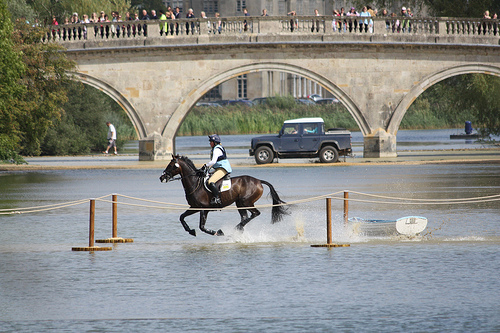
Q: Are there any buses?
A: No, there are no buses.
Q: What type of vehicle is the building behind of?
A: The building is behind the cars.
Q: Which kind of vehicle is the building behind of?
A: The building is behind the cars.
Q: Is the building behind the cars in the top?
A: Yes, the building is behind the cars.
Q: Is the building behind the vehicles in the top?
A: Yes, the building is behind the cars.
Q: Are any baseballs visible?
A: No, there are no baseballs.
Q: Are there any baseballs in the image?
A: No, there are no baseballs.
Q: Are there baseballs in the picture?
A: No, there are no baseballs.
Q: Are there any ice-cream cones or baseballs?
A: No, there are no baseballs or ice-cream cones.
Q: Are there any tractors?
A: No, there are no tractors.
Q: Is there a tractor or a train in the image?
A: No, there are no tractors or trains.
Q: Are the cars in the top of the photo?
A: Yes, the cars are in the top of the image.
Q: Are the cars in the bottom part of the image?
A: No, the cars are in the top of the image.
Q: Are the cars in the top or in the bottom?
A: The cars are in the top of the image.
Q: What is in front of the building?
A: The cars are in front of the building.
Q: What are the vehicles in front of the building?
A: The vehicles are cars.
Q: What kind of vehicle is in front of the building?
A: The vehicles are cars.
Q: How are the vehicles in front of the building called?
A: The vehicles are cars.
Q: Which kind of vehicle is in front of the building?
A: The vehicles are cars.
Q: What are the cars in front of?
A: The cars are in front of the building.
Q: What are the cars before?
A: The cars are in front of the building.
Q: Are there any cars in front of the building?
A: Yes, there are cars in front of the building.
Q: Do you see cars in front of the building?
A: Yes, there are cars in front of the building.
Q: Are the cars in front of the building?
A: Yes, the cars are in front of the building.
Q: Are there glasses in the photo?
A: No, there are no glasses.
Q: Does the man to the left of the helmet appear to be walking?
A: Yes, the man is walking.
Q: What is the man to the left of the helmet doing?
A: The man is walking.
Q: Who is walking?
A: The man is walking.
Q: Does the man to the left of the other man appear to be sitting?
A: No, the man is walking.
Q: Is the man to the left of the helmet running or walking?
A: The man is walking.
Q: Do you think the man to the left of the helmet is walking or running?
A: The man is walking.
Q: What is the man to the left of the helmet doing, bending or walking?
A: The man is walking.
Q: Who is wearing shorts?
A: The man is wearing shorts.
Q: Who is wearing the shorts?
A: The man is wearing shorts.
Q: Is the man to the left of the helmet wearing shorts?
A: Yes, the man is wearing shorts.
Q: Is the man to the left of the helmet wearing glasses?
A: No, the man is wearing shorts.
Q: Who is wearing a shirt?
A: The man is wearing a shirt.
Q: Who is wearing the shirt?
A: The man is wearing a shirt.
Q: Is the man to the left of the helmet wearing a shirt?
A: Yes, the man is wearing a shirt.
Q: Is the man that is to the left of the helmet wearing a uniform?
A: No, the man is wearing a shirt.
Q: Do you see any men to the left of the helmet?
A: Yes, there is a man to the left of the helmet.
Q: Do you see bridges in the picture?
A: Yes, there is a bridge.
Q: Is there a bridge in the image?
A: Yes, there is a bridge.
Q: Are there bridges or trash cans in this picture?
A: Yes, there is a bridge.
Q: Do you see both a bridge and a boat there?
A: Yes, there are both a bridge and a boat.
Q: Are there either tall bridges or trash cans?
A: Yes, there is a tall bridge.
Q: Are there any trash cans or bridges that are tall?
A: Yes, the bridge is tall.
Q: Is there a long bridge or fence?
A: Yes, there is a long bridge.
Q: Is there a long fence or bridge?
A: Yes, there is a long bridge.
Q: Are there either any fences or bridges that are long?
A: Yes, the bridge is long.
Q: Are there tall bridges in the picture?
A: Yes, there is a tall bridge.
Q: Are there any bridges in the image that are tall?
A: Yes, there is a bridge that is tall.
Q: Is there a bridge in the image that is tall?
A: Yes, there is a bridge that is tall.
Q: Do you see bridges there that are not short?
A: Yes, there is a tall bridge.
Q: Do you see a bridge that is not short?
A: Yes, there is a tall bridge.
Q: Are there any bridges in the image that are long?
A: Yes, there is a long bridge.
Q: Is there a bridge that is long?
A: Yes, there is a bridge that is long.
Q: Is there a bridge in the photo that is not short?
A: Yes, there is a long bridge.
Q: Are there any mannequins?
A: No, there are no mannequins.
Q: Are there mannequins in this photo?
A: No, there are no mannequins.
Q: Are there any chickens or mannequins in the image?
A: No, there are no mannequins or chickens.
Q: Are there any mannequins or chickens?
A: No, there are no mannequins or chickens.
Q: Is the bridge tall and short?
A: No, the bridge is tall but long.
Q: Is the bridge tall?
A: Yes, the bridge is tall.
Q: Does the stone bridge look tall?
A: Yes, the bridge is tall.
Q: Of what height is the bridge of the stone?
A: The bridge is tall.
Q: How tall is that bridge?
A: The bridge is tall.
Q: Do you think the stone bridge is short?
A: No, the bridge is tall.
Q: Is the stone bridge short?
A: No, the bridge is tall.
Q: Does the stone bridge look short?
A: No, the bridge is tall.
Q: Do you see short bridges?
A: No, there is a bridge but it is tall.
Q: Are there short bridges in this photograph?
A: No, there is a bridge but it is tall.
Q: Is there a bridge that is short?
A: No, there is a bridge but it is tall.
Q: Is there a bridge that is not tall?
A: No, there is a bridge but it is tall.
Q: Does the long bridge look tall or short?
A: The bridge is tall.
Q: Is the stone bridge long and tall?
A: Yes, the bridge is long and tall.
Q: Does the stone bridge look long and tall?
A: Yes, the bridge is long and tall.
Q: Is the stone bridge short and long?
A: No, the bridge is long but tall.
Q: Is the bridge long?
A: Yes, the bridge is long.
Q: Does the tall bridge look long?
A: Yes, the bridge is long.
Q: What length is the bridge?
A: The bridge is long.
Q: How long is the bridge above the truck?
A: The bridge is long.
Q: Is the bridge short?
A: No, the bridge is long.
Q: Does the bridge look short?
A: No, the bridge is long.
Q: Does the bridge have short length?
A: No, the bridge is long.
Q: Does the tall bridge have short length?
A: No, the bridge is long.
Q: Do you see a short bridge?
A: No, there is a bridge but it is long.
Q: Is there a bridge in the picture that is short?
A: No, there is a bridge but it is long.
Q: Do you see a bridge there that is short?
A: No, there is a bridge but it is long.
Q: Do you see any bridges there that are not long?
A: No, there is a bridge but it is long.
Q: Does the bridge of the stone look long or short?
A: The bridge is long.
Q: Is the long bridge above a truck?
A: Yes, the bridge is above a truck.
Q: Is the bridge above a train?
A: No, the bridge is above a truck.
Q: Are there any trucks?
A: Yes, there is a truck.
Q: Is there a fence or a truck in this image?
A: Yes, there is a truck.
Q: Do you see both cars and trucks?
A: Yes, there are both a truck and a car.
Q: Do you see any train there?
A: No, there are no trains.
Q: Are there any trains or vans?
A: No, there are no trains or vans.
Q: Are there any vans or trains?
A: No, there are no trains or vans.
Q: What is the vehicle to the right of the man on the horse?
A: The vehicle is a truck.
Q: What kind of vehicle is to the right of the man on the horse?
A: The vehicle is a truck.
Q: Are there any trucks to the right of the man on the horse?
A: Yes, there is a truck to the right of the man.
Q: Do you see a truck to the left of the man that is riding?
A: No, the truck is to the right of the man.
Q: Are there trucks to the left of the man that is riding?
A: No, the truck is to the right of the man.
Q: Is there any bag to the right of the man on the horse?
A: No, there is a truck to the right of the man.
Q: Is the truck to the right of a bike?
A: No, the truck is to the right of the man.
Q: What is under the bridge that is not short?
A: The truck is under the bridge.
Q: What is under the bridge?
A: The truck is under the bridge.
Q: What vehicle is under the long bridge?
A: The vehicle is a truck.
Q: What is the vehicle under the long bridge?
A: The vehicle is a truck.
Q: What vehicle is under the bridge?
A: The vehicle is a truck.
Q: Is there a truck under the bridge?
A: Yes, there is a truck under the bridge.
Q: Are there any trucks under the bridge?
A: Yes, there is a truck under the bridge.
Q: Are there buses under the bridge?
A: No, there is a truck under the bridge.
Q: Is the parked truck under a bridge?
A: Yes, the truck is under a bridge.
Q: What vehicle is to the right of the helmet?
A: The vehicle is a truck.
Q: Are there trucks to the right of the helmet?
A: Yes, there is a truck to the right of the helmet.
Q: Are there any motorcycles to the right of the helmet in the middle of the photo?
A: No, there is a truck to the right of the helmet.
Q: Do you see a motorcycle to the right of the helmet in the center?
A: No, there is a truck to the right of the helmet.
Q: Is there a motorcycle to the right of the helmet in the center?
A: No, there is a truck to the right of the helmet.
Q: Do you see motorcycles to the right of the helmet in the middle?
A: No, there is a truck to the right of the helmet.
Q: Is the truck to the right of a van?
A: No, the truck is to the right of a helmet.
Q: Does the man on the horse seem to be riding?
A: Yes, the man is riding.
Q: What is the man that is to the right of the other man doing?
A: The man is riding.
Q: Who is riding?
A: The man is riding.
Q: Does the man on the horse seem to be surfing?
A: No, the man is riding.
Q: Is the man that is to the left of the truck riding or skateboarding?
A: The man is riding.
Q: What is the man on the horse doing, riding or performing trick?
A: The man is riding.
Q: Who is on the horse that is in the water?
A: The man is on the horse.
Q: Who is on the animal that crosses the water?
A: The man is on the horse.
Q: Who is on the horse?
A: The man is on the horse.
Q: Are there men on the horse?
A: Yes, there is a man on the horse.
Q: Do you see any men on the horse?
A: Yes, there is a man on the horse.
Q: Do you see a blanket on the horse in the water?
A: No, there is a man on the horse.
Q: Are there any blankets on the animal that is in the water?
A: No, there is a man on the horse.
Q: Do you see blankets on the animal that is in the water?
A: No, there is a man on the horse.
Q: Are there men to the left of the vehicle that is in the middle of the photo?
A: Yes, there is a man to the left of the truck.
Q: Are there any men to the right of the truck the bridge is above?
A: No, the man is to the left of the truck.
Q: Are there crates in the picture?
A: No, there are no crates.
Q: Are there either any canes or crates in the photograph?
A: No, there are no crates or canes.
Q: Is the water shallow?
A: Yes, the water is shallow.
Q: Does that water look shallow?
A: Yes, the water is shallow.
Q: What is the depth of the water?
A: The water is shallow.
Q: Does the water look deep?
A: No, the water is shallow.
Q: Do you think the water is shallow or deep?
A: The water is shallow.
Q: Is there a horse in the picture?
A: Yes, there is a horse.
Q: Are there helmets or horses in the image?
A: Yes, there is a horse.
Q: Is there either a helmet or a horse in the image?
A: Yes, there is a horse.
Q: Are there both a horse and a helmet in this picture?
A: Yes, there are both a horse and a helmet.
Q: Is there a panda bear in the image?
A: No, there are no pandas.